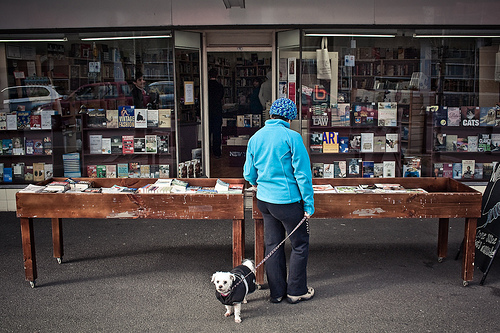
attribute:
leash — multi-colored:
[219, 215, 309, 290]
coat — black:
[229, 267, 262, 309]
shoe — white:
[285, 285, 315, 301]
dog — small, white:
[182, 256, 267, 331]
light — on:
[75, 27, 169, 45]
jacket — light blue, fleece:
[240, 127, 326, 213]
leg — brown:
[15, 226, 42, 272]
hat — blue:
[272, 89, 335, 122]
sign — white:
[181, 77, 198, 109]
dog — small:
[211, 258, 258, 322]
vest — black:
[231, 277, 250, 299]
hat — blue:
[267, 97, 299, 120]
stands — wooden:
[13, 175, 481, 288]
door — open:
[203, 47, 274, 188]